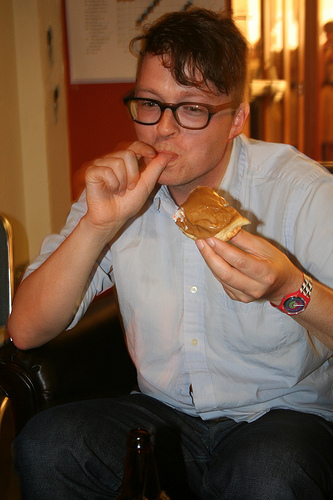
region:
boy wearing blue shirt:
[5, 5, 330, 484]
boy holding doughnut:
[7, 5, 331, 497]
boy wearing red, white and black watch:
[5, 4, 329, 487]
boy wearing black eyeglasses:
[6, 3, 332, 491]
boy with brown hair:
[9, 5, 330, 483]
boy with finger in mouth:
[4, 0, 330, 490]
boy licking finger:
[5, 5, 332, 493]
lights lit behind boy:
[225, 0, 314, 103]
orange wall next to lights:
[58, 0, 307, 216]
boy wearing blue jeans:
[6, 5, 332, 495]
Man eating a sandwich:
[15, 10, 330, 389]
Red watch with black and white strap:
[277, 272, 314, 329]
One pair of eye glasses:
[117, 90, 248, 131]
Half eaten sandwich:
[164, 180, 261, 247]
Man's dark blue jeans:
[2, 397, 330, 495]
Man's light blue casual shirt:
[11, 142, 322, 398]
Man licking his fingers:
[58, 1, 258, 228]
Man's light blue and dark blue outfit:
[0, 140, 331, 488]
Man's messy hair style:
[123, 2, 253, 98]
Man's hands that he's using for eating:
[78, 137, 283, 308]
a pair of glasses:
[129, 94, 207, 131]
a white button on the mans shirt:
[187, 336, 202, 348]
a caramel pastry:
[184, 188, 239, 235]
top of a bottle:
[126, 425, 152, 451]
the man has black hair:
[146, 9, 257, 82]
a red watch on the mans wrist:
[279, 268, 317, 319]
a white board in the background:
[61, 4, 125, 87]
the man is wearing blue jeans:
[31, 407, 110, 485]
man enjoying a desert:
[115, 12, 296, 400]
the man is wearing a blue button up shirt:
[85, 122, 323, 412]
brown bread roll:
[166, 182, 250, 248]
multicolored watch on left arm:
[260, 264, 317, 321]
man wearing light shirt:
[6, 6, 329, 497]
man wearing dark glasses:
[3, 4, 332, 458]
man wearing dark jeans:
[4, 0, 325, 496]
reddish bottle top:
[113, 420, 160, 498]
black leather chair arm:
[3, 284, 135, 413]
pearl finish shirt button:
[186, 280, 199, 298]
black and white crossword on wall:
[63, 0, 229, 92]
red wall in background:
[62, 6, 148, 181]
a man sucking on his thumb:
[57, 9, 262, 195]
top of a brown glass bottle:
[110, 420, 165, 498]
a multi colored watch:
[271, 272, 319, 317]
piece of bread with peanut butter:
[170, 178, 254, 244]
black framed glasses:
[118, 80, 240, 131]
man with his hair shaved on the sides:
[122, 6, 255, 193]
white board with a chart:
[67, 0, 240, 79]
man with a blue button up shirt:
[42, 4, 330, 403]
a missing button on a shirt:
[167, 371, 230, 414]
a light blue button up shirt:
[25, 134, 330, 421]